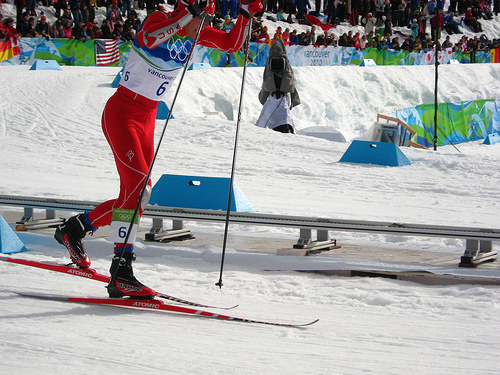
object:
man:
[50, 0, 265, 301]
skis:
[0, 249, 242, 310]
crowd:
[0, 0, 499, 51]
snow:
[0, 63, 500, 373]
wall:
[0, 38, 500, 79]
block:
[338, 140, 410, 168]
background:
[0, 0, 499, 68]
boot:
[106, 243, 156, 300]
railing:
[0, 37, 498, 68]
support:
[294, 228, 311, 247]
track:
[0, 195, 500, 268]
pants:
[85, 84, 163, 254]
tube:
[433, 0, 440, 151]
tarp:
[398, 99, 500, 149]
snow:
[345, 284, 463, 371]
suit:
[92, 0, 255, 247]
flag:
[94, 36, 119, 67]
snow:
[318, 73, 390, 113]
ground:
[1, 108, 500, 375]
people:
[62, 20, 75, 38]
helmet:
[173, 0, 215, 16]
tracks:
[31, 102, 64, 152]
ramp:
[337, 140, 411, 169]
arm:
[140, 14, 193, 47]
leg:
[100, 106, 153, 300]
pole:
[216, 19, 252, 290]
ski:
[0, 287, 320, 328]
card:
[140, 67, 179, 102]